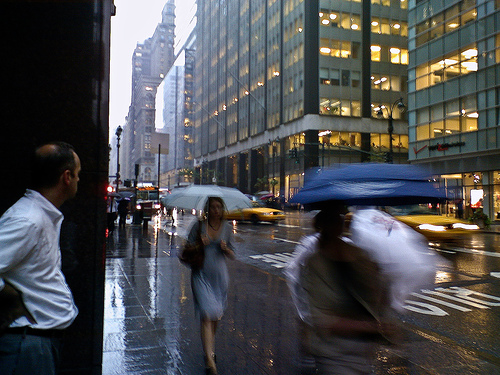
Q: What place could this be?
A: It is a street.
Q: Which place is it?
A: It is a street.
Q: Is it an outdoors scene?
A: Yes, it is outdoors.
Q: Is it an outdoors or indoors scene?
A: It is outdoors.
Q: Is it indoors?
A: No, it is outdoors.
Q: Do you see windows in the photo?
A: Yes, there is a window.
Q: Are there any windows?
A: Yes, there is a window.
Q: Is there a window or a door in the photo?
A: Yes, there is a window.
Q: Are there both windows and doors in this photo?
A: No, there is a window but no doors.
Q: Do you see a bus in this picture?
A: No, there are no buses.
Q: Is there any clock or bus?
A: No, there are no buses or clocks.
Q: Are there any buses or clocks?
A: No, there are no buses or clocks.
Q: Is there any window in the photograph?
A: Yes, there is a window.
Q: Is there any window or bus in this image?
A: Yes, there is a window.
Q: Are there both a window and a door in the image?
A: No, there is a window but no doors.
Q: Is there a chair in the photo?
A: No, there are no chairs.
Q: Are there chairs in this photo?
A: No, there are no chairs.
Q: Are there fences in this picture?
A: No, there are no fences.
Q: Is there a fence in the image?
A: No, there are no fences.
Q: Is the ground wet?
A: Yes, the ground is wet.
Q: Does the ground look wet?
A: Yes, the ground is wet.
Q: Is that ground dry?
A: No, the ground is wet.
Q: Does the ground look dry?
A: No, the ground is wet.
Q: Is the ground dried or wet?
A: The ground is wet.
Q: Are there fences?
A: No, there are no fences.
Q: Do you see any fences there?
A: No, there are no fences.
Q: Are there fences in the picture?
A: No, there are no fences.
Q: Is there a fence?
A: No, there are no fences.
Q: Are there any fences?
A: No, there are no fences.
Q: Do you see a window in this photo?
A: Yes, there is a window.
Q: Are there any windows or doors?
A: Yes, there is a window.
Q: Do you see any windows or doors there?
A: Yes, there is a window.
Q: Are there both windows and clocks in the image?
A: No, there is a window but no clocks.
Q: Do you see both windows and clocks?
A: No, there is a window but no clocks.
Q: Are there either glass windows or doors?
A: Yes, there is a glass window.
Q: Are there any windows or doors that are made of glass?
A: Yes, the window is made of glass.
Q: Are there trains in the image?
A: No, there are no trains.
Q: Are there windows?
A: Yes, there is a window.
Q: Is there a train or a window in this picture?
A: Yes, there is a window.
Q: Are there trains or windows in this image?
A: Yes, there is a window.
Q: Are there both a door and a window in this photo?
A: No, there is a window but no doors.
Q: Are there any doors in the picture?
A: No, there are no doors.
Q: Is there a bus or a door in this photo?
A: No, there are no doors or buses.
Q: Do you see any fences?
A: No, there are no fences.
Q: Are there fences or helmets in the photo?
A: No, there are no fences or helmets.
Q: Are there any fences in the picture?
A: No, there are no fences.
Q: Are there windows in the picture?
A: Yes, there is a window.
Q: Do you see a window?
A: Yes, there is a window.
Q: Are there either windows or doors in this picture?
A: Yes, there is a window.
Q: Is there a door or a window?
A: Yes, there is a window.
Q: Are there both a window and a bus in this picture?
A: No, there is a window but no buses.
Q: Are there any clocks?
A: No, there are no clocks.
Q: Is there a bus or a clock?
A: No, there are no clocks or buses.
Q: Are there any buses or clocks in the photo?
A: No, there are no clocks or buses.